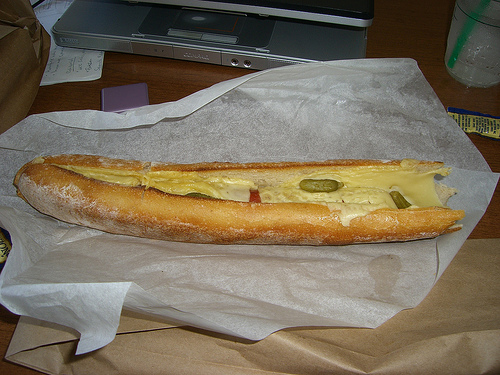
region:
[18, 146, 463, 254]
the sandwich on the bag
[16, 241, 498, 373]
the bag is brown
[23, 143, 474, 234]
the bread of the sandwich is toasted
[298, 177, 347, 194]
jalapeno in the sandwich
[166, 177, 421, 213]
cheese in the sandwich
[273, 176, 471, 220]
the cheese is melted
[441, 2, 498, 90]
beverage by the sandwich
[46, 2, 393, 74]
laptop by the sandwich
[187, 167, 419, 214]
Jalapenos in a sandwich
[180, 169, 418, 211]
Jalapenos are in a sandwich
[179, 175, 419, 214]
Sliced jalapenos in a sandwich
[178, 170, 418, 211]
Sliced jalapenos are in a sandwich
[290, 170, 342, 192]
Jalapeno in a sandwich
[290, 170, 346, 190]
Jalapeno is in a sandwich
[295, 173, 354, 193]
Sliced jalapeno in a sandwich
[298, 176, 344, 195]
Sliced jalapeno is in a sandwich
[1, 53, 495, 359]
Sandwich is on parchment paper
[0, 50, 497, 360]
Sandwich is on white parchment paper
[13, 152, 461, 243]
split baguette with egg cheese pickles and red bell pepper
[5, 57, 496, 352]
large sheet of cooking parchment paper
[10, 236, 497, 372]
brown wrapping paper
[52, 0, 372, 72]
silver electronic device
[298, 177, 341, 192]
green whole dill pickle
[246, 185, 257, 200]
piece of red bell pepper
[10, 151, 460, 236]
baguette sandwich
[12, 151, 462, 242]
crusty French baguette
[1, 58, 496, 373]
unwrapped baguette sandwich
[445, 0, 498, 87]
ice cold beverage with straw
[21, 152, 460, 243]
a sandwich is on the paper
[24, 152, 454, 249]
the bread is cut in half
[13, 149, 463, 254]
the bread is light brown in color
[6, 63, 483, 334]
a wax paper is under the bread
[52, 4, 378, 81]
a laptop is on the desk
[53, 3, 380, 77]
the laptop is grey in color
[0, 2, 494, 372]
the desk is made of wood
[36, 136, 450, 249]
a large cheesy sandwhich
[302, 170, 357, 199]
a piece of jalapeno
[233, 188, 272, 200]
a red piece of pepper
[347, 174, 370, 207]
a bunch of yellow cheese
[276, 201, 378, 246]
a long piece of bread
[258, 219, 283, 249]
the white flour on some bread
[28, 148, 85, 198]
the end of a sandwhich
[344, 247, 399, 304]
a grease stain on wax paper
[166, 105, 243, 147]
a piece of wax paper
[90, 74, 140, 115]
a little piece of scrap paper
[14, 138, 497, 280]
sandwich on the paper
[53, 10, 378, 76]
laptop on the table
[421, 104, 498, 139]
yellow and blue packet on the table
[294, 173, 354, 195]
jalapeno in the sandwich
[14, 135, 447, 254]
sandwich on the table